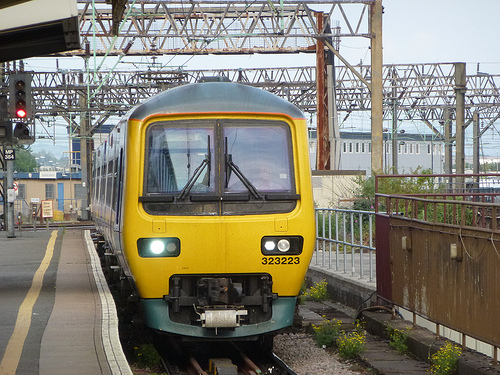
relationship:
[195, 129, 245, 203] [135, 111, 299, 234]
windshield wipers on windshield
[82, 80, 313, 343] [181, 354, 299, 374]
train on tracks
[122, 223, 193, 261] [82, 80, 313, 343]
light on train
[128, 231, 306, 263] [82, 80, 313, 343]
lights on train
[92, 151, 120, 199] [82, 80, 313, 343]
window of train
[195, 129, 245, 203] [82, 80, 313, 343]
windshield wipers on train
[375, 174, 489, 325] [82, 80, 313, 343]
fence by train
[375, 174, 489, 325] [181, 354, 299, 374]
fence by tracks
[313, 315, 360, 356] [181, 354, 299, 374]
weeds growing near tracks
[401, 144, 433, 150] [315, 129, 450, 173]
windows on building